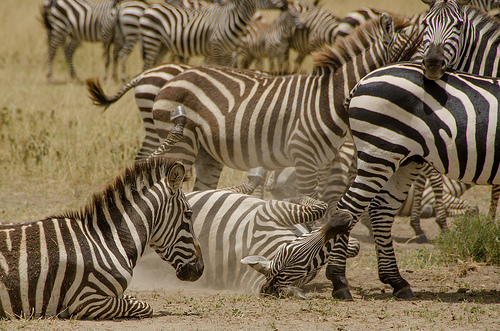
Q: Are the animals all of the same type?
A: Yes, all the animals are zebras.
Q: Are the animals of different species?
A: No, all the animals are zebras.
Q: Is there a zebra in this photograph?
A: Yes, there is a zebra.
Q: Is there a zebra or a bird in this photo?
A: Yes, there is a zebra.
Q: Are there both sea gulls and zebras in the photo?
A: No, there is a zebra but no seagulls.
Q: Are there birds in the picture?
A: No, there are no birds.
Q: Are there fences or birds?
A: No, there are no birds or fences.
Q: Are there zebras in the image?
A: Yes, there is a zebra.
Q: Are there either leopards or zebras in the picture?
A: Yes, there is a zebra.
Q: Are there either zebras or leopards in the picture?
A: Yes, there is a zebra.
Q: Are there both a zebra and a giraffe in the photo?
A: No, there is a zebra but no giraffes.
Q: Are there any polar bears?
A: No, there are no polar bears.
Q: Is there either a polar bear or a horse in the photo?
A: No, there are no polar bears or horses.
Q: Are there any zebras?
A: Yes, there is a zebra.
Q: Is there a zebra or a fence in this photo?
A: Yes, there is a zebra.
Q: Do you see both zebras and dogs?
A: No, there is a zebra but no dogs.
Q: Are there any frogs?
A: No, there are no frogs.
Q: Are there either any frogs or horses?
A: No, there are no frogs or horses.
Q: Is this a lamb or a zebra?
A: This is a zebra.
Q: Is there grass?
A: Yes, there is grass.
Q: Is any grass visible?
A: Yes, there is grass.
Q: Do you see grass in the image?
A: Yes, there is grass.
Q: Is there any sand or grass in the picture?
A: Yes, there is grass.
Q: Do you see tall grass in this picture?
A: Yes, there is tall grass.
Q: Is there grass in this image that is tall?
A: Yes, there is grass that is tall.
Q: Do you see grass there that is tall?
A: Yes, there is grass that is tall.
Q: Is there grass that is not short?
A: Yes, there is tall grass.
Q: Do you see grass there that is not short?
A: Yes, there is tall grass.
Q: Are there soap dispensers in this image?
A: No, there are no soap dispensers.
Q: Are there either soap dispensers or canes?
A: No, there are no soap dispensers or canes.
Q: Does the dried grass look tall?
A: Yes, the grass is tall.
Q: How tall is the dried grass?
A: The grass is tall.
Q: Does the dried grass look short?
A: No, the grass is tall.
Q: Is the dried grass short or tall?
A: The grass is tall.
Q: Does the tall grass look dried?
A: Yes, the grass is dried.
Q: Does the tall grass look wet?
A: No, the grass is dried.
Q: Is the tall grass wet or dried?
A: The grass is dried.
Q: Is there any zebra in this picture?
A: Yes, there is a zebra.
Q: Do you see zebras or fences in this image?
A: Yes, there is a zebra.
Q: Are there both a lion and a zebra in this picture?
A: No, there is a zebra but no lions.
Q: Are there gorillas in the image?
A: No, there are no gorillas.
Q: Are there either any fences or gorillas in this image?
A: No, there are no gorillas or fences.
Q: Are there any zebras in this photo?
A: Yes, there is a zebra.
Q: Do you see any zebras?
A: Yes, there is a zebra.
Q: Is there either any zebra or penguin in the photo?
A: Yes, there is a zebra.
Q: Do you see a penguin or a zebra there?
A: Yes, there is a zebra.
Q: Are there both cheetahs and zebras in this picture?
A: No, there is a zebra but no cheetahs.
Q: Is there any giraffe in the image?
A: No, there are no giraffes.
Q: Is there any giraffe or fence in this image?
A: No, there are no giraffes or fences.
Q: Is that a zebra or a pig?
A: That is a zebra.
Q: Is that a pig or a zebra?
A: That is a zebra.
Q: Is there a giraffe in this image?
A: No, there are no giraffes.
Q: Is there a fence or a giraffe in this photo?
A: No, there are no giraffes or fences.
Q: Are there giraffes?
A: No, there are no giraffes.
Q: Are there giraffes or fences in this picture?
A: No, there are no giraffes or fences.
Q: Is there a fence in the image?
A: No, there are no fences.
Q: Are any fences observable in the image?
A: No, there are no fences.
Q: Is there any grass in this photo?
A: Yes, there is grass.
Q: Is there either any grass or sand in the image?
A: Yes, there is grass.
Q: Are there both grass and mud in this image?
A: No, there is grass but no mud.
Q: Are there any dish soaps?
A: No, there are no dish soaps.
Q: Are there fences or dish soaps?
A: No, there are no dish soaps or fences.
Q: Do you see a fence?
A: No, there are no fences.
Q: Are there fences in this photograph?
A: No, there are no fences.